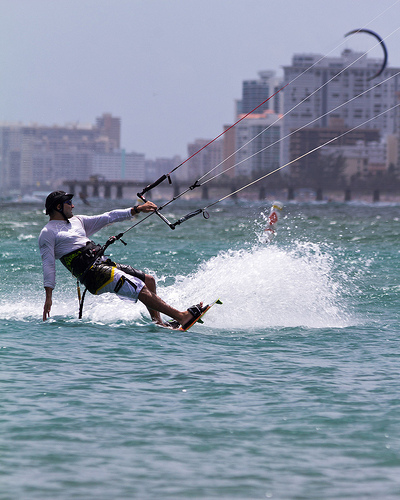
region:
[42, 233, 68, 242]
man wears white shirt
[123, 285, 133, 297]
man wears white shorts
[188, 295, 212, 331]
man wears black slippers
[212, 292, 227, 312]
black flag on slippers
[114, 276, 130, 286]
black design on shorts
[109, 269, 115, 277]
yellow design on shorts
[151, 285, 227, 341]
mans feet in water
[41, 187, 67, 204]
man wears black hat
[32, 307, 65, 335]
mans hand in water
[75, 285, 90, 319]
black strap behind man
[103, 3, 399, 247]
the control lines for the kite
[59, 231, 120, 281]
the control line harness is black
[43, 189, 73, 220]
a black safety helmet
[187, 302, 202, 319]
the kite board foot strap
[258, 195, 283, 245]
a waterway marker buoy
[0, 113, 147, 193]
city buildings in the distance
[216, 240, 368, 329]
a white water wake formed by the kite board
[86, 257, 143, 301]
the kiteboarder is wearing black and white shorts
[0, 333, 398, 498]
the water is calm in the foreground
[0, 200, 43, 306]
the water is choppy and rough in the distance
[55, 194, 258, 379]
the man is wet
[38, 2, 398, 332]
a man kite surfboarding on the water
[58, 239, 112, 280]
a belt gear attached to the kite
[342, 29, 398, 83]
another kite in the air for surfboarding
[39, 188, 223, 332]
a man pulled on the water by a kite in the air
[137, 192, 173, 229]
hand rods to hold the kite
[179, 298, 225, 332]
the tip of a surfboard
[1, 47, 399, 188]
buildings on the side of the lake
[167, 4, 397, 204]
four lines attached to the kite and belt gear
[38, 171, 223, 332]
a surfer leaning backward on a surfboard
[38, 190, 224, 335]
a man holding the kite rod with one hand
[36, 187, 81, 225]
man has black hat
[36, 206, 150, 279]
man has white shirt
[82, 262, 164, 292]
man has white pants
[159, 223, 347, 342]
board kicking up water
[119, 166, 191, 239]
man is holding bar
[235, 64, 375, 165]
tall buildings in background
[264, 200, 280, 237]
red buoy in water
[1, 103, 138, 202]
brown building in background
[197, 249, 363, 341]
water splashing beside man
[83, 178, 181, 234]
man holds on to kite